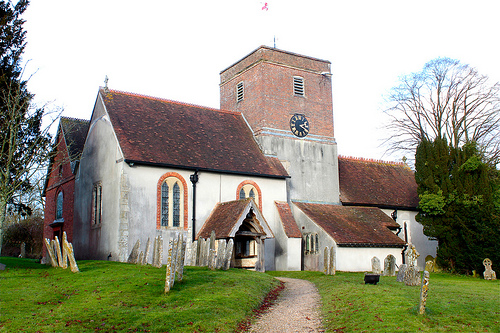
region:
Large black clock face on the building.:
[282, 105, 317, 141]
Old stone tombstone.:
[472, 251, 498, 283]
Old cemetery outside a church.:
[318, 235, 498, 318]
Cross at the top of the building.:
[94, 70, 116, 102]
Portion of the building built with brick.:
[213, 42, 344, 138]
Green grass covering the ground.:
[7, 267, 162, 330]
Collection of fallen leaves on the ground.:
[250, 277, 294, 317]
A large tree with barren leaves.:
[385, 51, 498, 159]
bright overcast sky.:
[28, 7, 220, 95]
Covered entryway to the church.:
[203, 197, 282, 274]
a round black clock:
[282, 112, 319, 136]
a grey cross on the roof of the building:
[98, 66, 113, 98]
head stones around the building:
[27, 225, 240, 292]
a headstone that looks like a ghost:
[474, 250, 497, 285]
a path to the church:
[237, 263, 347, 331]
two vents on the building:
[214, 64, 313, 104]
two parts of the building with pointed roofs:
[20, 78, 268, 262]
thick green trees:
[414, 132, 498, 277]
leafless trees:
[390, 57, 499, 154]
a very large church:
[31, 35, 458, 302]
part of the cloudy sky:
[357, 0, 437, 37]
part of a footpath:
[281, 280, 322, 317]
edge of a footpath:
[251, 286, 272, 314]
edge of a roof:
[151, 151, 182, 176]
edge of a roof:
[125, 143, 163, 170]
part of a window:
[83, 187, 107, 218]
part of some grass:
[97, 266, 140, 309]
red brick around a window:
[130, 152, 205, 247]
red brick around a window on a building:
[131, 152, 211, 247]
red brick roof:
[97, 89, 286, 190]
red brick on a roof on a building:
[96, 91, 291, 187]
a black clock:
[266, 105, 324, 137]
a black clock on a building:
[260, 96, 398, 271]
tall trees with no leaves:
[373, 60, 495, 257]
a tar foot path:
[225, 255, 346, 330]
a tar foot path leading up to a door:
[180, 215, 347, 327]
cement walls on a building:
[66, 75, 304, 270]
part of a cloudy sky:
[356, 0, 393, 17]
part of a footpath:
[286, 266, 307, 301]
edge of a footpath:
[253, 274, 278, 311]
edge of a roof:
[341, 236, 368, 247]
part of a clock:
[291, 132, 308, 145]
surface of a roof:
[185, 140, 227, 167]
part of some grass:
[372, 304, 396, 326]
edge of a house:
[93, 203, 131, 253]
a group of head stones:
[362, 231, 499, 288]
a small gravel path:
[249, 265, 322, 331]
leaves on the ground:
[23, 260, 216, 331]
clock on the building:
[285, 116, 312, 139]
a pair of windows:
[150, 178, 187, 231]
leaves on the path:
[242, 263, 287, 331]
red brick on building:
[23, 134, 78, 239]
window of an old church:
[158, 178, 169, 229]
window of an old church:
[171, 181, 179, 228]